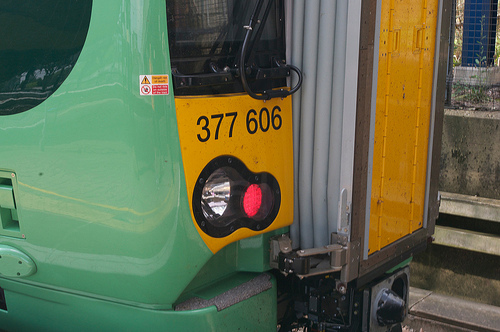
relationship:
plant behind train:
[470, 12, 491, 107] [1, 4, 458, 330]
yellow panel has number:
[175, 87, 293, 253] [211, 113, 226, 140]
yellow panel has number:
[175, 87, 293, 253] [224, 112, 236, 134]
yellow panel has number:
[175, 87, 293, 253] [246, 109, 256, 132]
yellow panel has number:
[175, 87, 293, 253] [258, 107, 269, 132]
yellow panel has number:
[175, 87, 293, 253] [271, 105, 281, 130]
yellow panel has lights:
[175, 87, 293, 253] [203, 167, 230, 218]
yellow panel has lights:
[175, 87, 293, 253] [242, 184, 263, 216]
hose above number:
[234, 0, 312, 112] [186, 100, 287, 141]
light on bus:
[242, 185, 269, 220] [0, 1, 457, 327]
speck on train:
[32, 161, 52, 189] [1, 4, 458, 330]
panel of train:
[1, 2, 283, 329] [1, 4, 458, 330]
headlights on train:
[191, 154, 277, 231] [1, 4, 458, 330]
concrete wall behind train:
[439, 110, 499, 256] [1, 4, 458, 330]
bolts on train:
[16, 259, 23, 278] [1, 4, 458, 330]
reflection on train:
[49, 165, 163, 242] [1, 4, 458, 330]